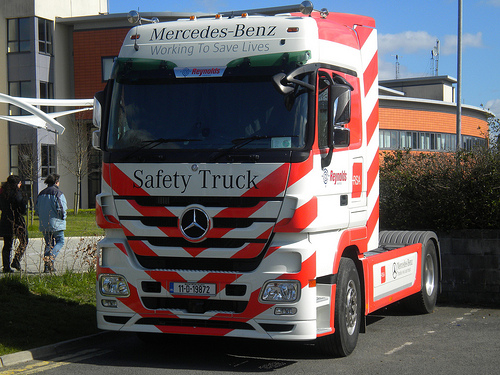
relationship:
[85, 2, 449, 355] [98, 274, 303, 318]
truck cab has headlights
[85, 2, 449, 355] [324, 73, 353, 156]
truck cab has side mirror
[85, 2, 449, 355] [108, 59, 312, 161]
truck cab has windshield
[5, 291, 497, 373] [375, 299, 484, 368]
parking lot has faded markings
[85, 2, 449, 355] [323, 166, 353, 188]
truck cab has reynolds logo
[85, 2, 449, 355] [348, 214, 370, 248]
truck cab has stepup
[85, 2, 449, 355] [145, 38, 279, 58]
truck cab has lettering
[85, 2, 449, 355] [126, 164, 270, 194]
truck cab says safety truck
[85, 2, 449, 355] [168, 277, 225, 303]
truck cab has license plate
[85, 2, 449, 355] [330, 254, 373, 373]
truck cab has tire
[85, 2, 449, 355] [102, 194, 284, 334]
truck cab has grill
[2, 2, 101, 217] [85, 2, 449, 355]
building behind truck cab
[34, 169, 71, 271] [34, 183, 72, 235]
girl wearing blue coat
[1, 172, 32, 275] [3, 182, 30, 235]
girl wearing black coat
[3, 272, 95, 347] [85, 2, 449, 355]
grass beside truck cab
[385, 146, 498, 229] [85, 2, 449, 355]
bushes are behind truck cab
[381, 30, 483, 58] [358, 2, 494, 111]
clouds are in sky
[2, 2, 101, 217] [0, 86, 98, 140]
building has white overhang